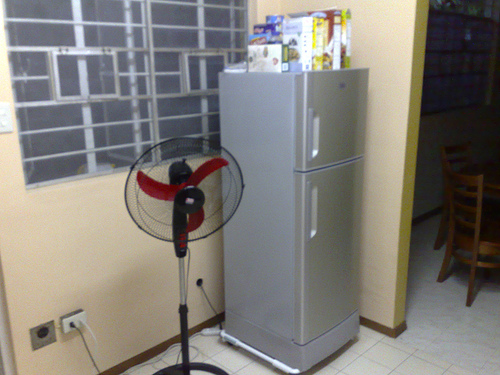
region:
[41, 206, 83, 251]
this is a wall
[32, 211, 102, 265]
the wall is white in color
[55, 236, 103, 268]
the wall is clean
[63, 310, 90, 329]
this is a socket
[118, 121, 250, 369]
this is a fan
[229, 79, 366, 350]
this is a fridge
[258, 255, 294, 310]
the fridge is grey in color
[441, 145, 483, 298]
this is a chair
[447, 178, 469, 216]
the chair is wooden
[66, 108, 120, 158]
this is a window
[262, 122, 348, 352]
the fridge is silvery in color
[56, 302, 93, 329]
the socket is white in color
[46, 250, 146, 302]
the wall is brown in color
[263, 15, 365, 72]
the packets are on top of the fridge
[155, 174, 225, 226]
tha fan has red wings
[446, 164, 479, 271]
the chairs are wooden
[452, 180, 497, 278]
the chairs are brown in color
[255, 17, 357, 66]
the packets are multicolored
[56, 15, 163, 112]
the windows are white in color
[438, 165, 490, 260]
the seats are brown in color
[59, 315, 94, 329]
the socket is white in color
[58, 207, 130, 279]
the wall is lime white in color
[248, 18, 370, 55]
the foodstuffs ar on the fridge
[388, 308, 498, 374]
the fkloor has white tiles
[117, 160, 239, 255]
the air pangs is beside the fridge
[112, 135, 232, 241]
the air fan is black in color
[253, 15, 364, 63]
the packet are multicolored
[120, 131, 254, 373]
black and red standing fan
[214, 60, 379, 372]
stainless colored refrigerator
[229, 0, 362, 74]
several boxes of cereal on top of refrigerator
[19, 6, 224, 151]
windows with white bar framed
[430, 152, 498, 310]
wooden chairs under table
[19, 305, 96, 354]
two electric outlets on wall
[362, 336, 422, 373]
white tiled kitchen floor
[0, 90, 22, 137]
white power switches on wall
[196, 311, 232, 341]
white surge protector on floor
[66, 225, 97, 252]
yellow painted wall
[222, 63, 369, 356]
the fridge is silver in color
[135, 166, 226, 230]
the fan is red in color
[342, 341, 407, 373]
the tiles are white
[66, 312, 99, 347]
the cable is white and black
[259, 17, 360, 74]
cereal boxes are on the fridge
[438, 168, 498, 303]
the chair is wooden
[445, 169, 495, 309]
the chair is brown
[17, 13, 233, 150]
the window is grilled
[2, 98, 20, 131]
the switch is white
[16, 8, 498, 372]
the room is in the kitchen